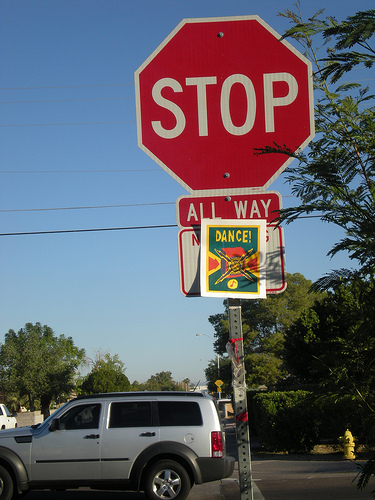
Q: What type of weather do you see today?
A: It is clear.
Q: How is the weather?
A: It is clear.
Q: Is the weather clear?
A: Yes, it is clear.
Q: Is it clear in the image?
A: Yes, it is clear.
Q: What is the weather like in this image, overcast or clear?
A: It is clear.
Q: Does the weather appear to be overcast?
A: No, it is clear.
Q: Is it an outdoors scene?
A: Yes, it is outdoors.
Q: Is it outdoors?
A: Yes, it is outdoors.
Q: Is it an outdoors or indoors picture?
A: It is outdoors.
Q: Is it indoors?
A: No, it is outdoors.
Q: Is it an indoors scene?
A: No, it is outdoors.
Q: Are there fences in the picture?
A: No, there are no fences.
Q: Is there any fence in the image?
A: No, there are no fences.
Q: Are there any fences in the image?
A: No, there are no fences.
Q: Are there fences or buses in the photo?
A: No, there are no fences or buses.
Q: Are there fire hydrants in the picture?
A: Yes, there is a fire hydrant.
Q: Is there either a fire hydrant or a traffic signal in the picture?
A: Yes, there is a fire hydrant.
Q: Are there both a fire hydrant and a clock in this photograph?
A: No, there is a fire hydrant but no clocks.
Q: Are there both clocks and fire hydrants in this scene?
A: No, there is a fire hydrant but no clocks.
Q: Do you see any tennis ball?
A: No, there are no tennis balls.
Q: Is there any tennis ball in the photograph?
A: No, there are no tennis balls.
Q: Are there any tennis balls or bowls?
A: No, there are no tennis balls or bowls.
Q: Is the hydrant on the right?
A: Yes, the hydrant is on the right of the image.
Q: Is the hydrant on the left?
A: No, the hydrant is on the right of the image.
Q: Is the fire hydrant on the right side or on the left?
A: The fire hydrant is on the right of the image.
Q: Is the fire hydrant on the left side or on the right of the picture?
A: The fire hydrant is on the right of the image.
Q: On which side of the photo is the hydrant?
A: The hydrant is on the right of the image.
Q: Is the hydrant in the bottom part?
A: Yes, the hydrant is in the bottom of the image.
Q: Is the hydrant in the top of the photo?
A: No, the hydrant is in the bottom of the image.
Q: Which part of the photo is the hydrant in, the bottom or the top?
A: The hydrant is in the bottom of the image.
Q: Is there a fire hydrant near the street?
A: Yes, there is a fire hydrant near the street.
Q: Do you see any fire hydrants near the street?
A: Yes, there is a fire hydrant near the street.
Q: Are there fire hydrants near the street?
A: Yes, there is a fire hydrant near the street.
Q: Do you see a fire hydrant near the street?
A: Yes, there is a fire hydrant near the street.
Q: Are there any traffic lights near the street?
A: No, there is a fire hydrant near the street.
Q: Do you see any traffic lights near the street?
A: No, there is a fire hydrant near the street.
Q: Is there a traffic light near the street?
A: No, there is a fire hydrant near the street.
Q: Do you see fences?
A: No, there are no fences.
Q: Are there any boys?
A: No, there are no boys.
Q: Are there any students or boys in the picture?
A: No, there are no boys or students.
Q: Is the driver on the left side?
A: Yes, the driver is on the left of the image.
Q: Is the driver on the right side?
A: No, the driver is on the left of the image.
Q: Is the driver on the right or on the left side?
A: The driver is on the left of the image.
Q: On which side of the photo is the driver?
A: The driver is on the left of the image.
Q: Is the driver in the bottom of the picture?
A: Yes, the driver is in the bottom of the image.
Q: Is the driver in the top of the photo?
A: No, the driver is in the bottom of the image.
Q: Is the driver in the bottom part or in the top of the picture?
A: The driver is in the bottom of the image.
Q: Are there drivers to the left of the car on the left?
A: No, the driver is to the right of the car.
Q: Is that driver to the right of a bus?
A: No, the driver is to the right of the car.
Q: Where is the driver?
A: The driver is in the car.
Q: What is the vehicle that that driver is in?
A: The vehicle is a car.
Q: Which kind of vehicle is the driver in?
A: The driver is in the car.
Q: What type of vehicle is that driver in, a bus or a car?
A: The driver is in a car.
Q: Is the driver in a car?
A: Yes, the driver is in a car.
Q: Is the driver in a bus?
A: No, the driver is in a car.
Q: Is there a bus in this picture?
A: No, there are no buses.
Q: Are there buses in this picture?
A: No, there are no buses.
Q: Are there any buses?
A: No, there are no buses.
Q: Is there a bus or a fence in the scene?
A: No, there are no buses or fences.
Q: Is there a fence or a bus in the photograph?
A: No, there are no buses or fences.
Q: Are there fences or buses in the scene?
A: No, there are no buses or fences.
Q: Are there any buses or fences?
A: No, there are no buses or fences.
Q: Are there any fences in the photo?
A: No, there are no fences.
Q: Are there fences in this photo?
A: No, there are no fences.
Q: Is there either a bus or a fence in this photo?
A: No, there are no fences or buses.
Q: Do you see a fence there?
A: No, there are no fences.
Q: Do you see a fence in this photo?
A: No, there are no fences.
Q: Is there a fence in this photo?
A: No, there are no fences.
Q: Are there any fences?
A: No, there are no fences.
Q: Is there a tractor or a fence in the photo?
A: No, there are no fences or tractors.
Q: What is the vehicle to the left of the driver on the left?
A: The vehicle is a car.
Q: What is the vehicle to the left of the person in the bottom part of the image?
A: The vehicle is a car.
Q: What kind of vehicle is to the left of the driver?
A: The vehicle is a car.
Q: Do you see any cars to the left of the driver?
A: Yes, there is a car to the left of the driver.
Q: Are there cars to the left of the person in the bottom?
A: Yes, there is a car to the left of the driver.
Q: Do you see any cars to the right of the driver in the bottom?
A: No, the car is to the left of the driver.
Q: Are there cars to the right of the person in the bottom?
A: No, the car is to the left of the driver.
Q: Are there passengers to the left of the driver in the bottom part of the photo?
A: No, there is a car to the left of the driver.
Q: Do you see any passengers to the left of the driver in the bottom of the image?
A: No, there is a car to the left of the driver.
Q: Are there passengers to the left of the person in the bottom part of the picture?
A: No, there is a car to the left of the driver.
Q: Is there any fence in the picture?
A: No, there are no fences.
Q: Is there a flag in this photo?
A: No, there are no flags.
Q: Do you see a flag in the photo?
A: No, there are no flags.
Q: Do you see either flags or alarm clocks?
A: No, there are no flags or alarm clocks.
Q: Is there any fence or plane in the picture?
A: No, there are no fences or airplanes.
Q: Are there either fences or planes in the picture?
A: No, there are no fences or planes.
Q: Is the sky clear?
A: Yes, the sky is clear.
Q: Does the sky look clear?
A: Yes, the sky is clear.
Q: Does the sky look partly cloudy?
A: No, the sky is clear.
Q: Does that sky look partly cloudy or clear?
A: The sky is clear.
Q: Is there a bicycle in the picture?
A: No, there are no bicycles.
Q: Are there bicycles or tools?
A: No, there are no bicycles or tools.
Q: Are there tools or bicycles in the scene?
A: No, there are no bicycles or tools.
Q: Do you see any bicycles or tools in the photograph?
A: No, there are no bicycles or tools.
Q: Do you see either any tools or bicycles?
A: No, there are no bicycles or tools.